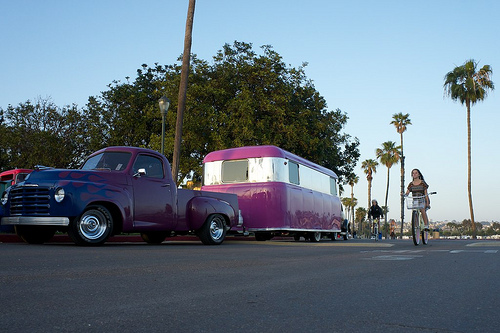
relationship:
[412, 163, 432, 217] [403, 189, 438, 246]
woman riding bicycle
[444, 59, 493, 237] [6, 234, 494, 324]
palm tree near street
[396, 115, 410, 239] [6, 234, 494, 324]
palm tree near street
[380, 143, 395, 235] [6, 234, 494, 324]
palm tree near street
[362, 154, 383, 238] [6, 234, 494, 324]
palm tree near street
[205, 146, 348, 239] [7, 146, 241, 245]
purple trailer on truck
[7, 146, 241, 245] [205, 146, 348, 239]
truck pulling purple trailer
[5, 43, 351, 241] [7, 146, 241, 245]
trees behind truck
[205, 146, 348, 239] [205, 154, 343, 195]
purple trailer has white section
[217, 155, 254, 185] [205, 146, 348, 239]
window of purple trailer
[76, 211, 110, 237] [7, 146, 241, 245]
rim on truck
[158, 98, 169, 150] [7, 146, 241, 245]
lamo post behind truck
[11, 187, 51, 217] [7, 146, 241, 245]
grill of truck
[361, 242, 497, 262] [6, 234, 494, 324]
white lines on street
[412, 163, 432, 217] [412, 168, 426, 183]
woman has dark hair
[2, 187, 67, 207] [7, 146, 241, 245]
headlights on truck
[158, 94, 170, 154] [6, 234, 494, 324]
lamo post on street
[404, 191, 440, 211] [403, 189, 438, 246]
basket on bicycle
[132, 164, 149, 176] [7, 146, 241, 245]
mirror on truck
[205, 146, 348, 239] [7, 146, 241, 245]
purple trailer behind truck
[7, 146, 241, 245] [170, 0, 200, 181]
truck near pole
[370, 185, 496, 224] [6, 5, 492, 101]
clouds in sky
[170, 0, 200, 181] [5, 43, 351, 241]
pole near trees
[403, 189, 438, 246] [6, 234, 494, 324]
bicycle on street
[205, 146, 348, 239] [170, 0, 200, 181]
purple trailer near pole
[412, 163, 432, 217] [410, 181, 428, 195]
woman wearing brown shirt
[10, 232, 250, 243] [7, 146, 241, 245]
curb under truck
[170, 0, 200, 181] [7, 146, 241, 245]
pole behind truck